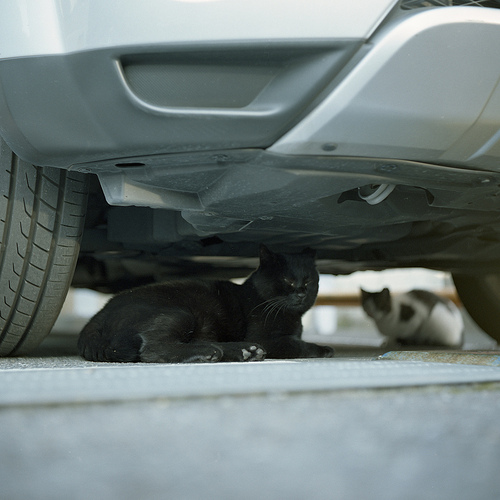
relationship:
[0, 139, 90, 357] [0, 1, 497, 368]
tire of car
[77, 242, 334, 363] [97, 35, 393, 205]
cats under car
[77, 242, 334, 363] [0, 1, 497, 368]
cats under a car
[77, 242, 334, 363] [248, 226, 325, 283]
cats has ears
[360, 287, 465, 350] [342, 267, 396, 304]
cat has ears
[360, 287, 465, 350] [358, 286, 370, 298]
cat has ear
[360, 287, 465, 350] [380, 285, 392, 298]
cat has ear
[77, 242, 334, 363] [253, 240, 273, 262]
cats has ear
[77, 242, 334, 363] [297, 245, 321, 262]
cats has ear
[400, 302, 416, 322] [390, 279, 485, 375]
spots on cat's back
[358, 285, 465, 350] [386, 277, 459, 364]
cat has back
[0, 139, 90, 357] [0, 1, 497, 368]
tire on car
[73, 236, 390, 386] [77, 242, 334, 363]
hair on cats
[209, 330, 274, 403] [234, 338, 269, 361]
bottom pad on paw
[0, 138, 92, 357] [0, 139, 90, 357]
tread on tire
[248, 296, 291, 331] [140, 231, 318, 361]
whiskers on cat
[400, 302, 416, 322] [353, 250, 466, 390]
spots on cat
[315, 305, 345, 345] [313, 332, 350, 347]
bucket on ground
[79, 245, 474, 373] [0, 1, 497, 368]
cats under car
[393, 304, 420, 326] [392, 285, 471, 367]
spots on back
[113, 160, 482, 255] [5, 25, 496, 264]
undercarriage on car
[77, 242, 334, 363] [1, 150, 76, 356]
cats next to tire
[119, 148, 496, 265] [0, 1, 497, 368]
bottom of a car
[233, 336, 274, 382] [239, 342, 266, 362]
bottom of a paw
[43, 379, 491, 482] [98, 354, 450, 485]
part of a parking lot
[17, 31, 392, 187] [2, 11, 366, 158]
bottom part of a car bumper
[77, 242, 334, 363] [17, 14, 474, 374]
cats under a car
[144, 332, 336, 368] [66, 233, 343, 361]
legs of a cat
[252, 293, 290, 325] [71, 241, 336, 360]
whiskers of a cat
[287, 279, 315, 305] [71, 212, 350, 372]
nose of a cat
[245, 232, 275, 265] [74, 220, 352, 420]
ears of a cat